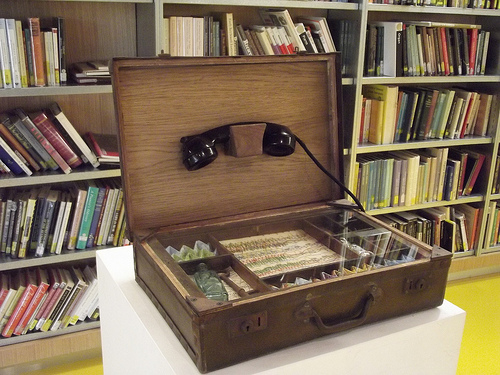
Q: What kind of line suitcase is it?
A: Antique wood.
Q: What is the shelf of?
A: Library books.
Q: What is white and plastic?
A: Display stand.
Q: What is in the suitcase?
A: A locker.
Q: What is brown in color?
A: The locker.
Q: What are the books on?
A: A shelf.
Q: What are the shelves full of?
A: Books.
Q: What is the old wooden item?
A: Briefcase.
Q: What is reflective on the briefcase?
A: Glass.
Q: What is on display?
A: Briefcase.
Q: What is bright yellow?
A: Floor.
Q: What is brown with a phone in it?
A: Briefcase.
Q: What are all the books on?
A: Shelves.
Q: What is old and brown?
A: Briefcase.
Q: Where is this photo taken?
A: In a library.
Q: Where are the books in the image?
A: On shelves.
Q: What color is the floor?
A: Yellow.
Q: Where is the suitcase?
A: On a pedestal.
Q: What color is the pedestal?
A: White.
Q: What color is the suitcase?
A: Brown.